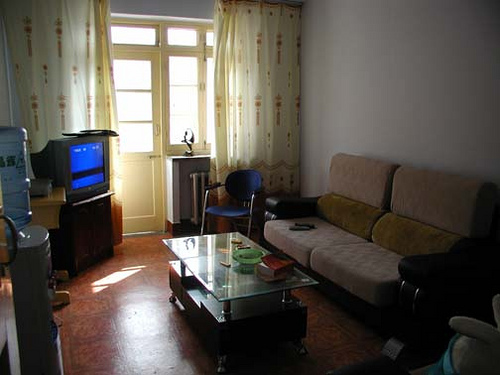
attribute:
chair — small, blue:
[196, 166, 276, 238]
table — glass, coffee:
[154, 219, 318, 367]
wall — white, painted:
[298, 2, 499, 219]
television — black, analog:
[27, 134, 110, 201]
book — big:
[243, 246, 303, 290]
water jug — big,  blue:
[2, 123, 36, 244]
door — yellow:
[101, 36, 204, 248]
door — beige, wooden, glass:
[157, 51, 204, 239]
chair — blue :
[192, 153, 284, 250]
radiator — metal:
[188, 165, 210, 227]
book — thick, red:
[252, 250, 295, 279]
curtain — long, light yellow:
[209, 0, 304, 197]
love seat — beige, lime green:
[262, 146, 499, 331]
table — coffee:
[118, 203, 318, 338]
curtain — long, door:
[18, 10, 150, 125]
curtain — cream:
[213, 2, 313, 197]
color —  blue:
[72, 147, 107, 187]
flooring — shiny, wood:
[35, 221, 401, 368]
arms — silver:
[195, 176, 261, 239]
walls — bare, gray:
[301, 5, 494, 212]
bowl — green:
[234, 246, 264, 272]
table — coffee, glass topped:
[163, 226, 322, 367]